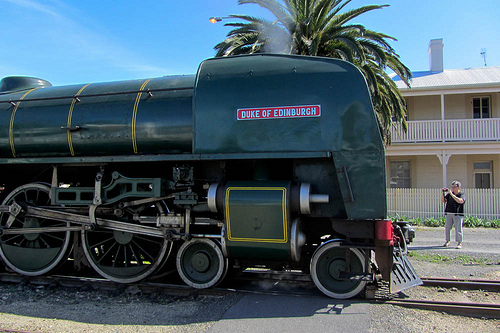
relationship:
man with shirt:
[435, 181, 466, 246] [443, 193, 463, 213]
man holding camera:
[435, 181, 466, 246] [442, 185, 449, 192]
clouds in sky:
[80, 25, 142, 63] [0, 1, 500, 85]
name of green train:
[235, 102, 321, 120] [0, 50, 425, 302]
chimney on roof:
[427, 37, 445, 72] [380, 65, 498, 92]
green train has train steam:
[0, 50, 425, 302] [258, 0, 308, 56]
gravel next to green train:
[8, 277, 222, 330] [0, 50, 425, 302]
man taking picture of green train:
[441, 181, 468, 249] [0, 50, 425, 302]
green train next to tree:
[0, 50, 425, 302] [209, 1, 427, 178]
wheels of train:
[4, 159, 396, 323] [21, 70, 408, 330]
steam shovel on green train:
[381, 245, 426, 297] [0, 50, 425, 302]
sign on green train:
[237, 104, 321, 119] [0, 50, 425, 302]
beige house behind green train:
[381, 38, 499, 227] [0, 50, 425, 302]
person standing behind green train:
[438, 168, 480, 250] [0, 50, 425, 302]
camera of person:
[430, 181, 452, 198] [440, 179, 469, 249]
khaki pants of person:
[443, 212, 463, 242] [439, 178, 466, 249]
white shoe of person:
[442, 238, 450, 245] [436, 177, 471, 249]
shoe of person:
[455, 243, 462, 248] [436, 177, 471, 249]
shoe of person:
[455, 235, 462, 247] [435, 176, 468, 250]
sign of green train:
[237, 104, 321, 119] [0, 50, 425, 302]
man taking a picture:
[441, 181, 468, 249] [4, 8, 498, 329]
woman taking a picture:
[438, 176, 473, 246] [428, 183, 469, 210]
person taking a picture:
[438, 179, 467, 250] [433, 172, 460, 206]